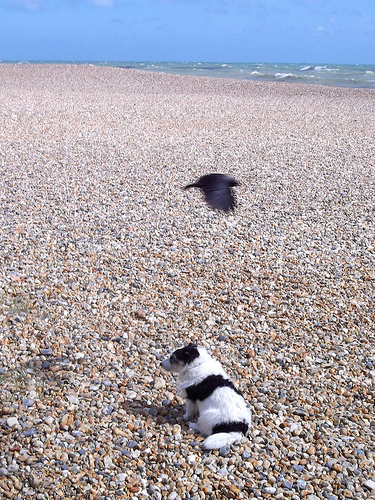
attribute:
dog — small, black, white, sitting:
[159, 343, 251, 451]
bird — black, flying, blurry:
[181, 172, 241, 216]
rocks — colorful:
[1, 64, 374, 499]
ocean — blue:
[0, 59, 373, 88]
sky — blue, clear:
[0, 0, 374, 67]